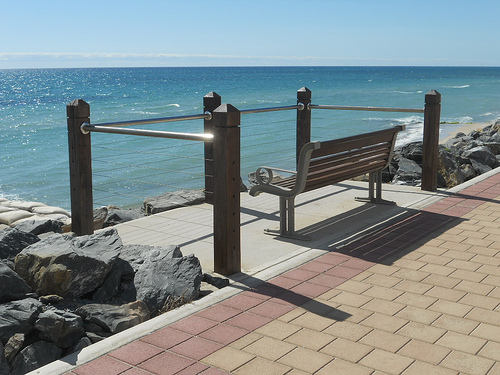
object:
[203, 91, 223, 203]
pole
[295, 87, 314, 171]
pole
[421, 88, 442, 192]
pole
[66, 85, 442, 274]
railing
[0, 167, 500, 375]
walkway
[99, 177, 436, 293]
cement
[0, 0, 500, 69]
blue sky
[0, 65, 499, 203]
ocean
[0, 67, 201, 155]
ripples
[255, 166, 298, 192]
armrest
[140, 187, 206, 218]
rocks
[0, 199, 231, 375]
rocks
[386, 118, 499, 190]
rocks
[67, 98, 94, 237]
pole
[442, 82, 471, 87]
waves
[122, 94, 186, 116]
waves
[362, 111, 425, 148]
waves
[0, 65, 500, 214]
water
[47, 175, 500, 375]
brick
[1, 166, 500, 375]
ground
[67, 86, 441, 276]
fence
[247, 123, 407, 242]
bench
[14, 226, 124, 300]
large rock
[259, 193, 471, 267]
shadow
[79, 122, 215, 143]
metal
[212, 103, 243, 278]
post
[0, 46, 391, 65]
cloud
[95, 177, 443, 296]
concrete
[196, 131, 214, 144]
sun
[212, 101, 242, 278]
pole